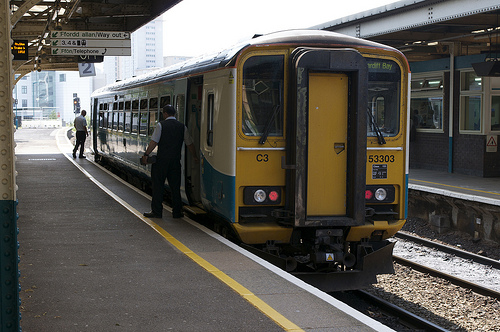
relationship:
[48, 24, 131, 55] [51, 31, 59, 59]
sign has arrows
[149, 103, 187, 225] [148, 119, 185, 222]
man wearing uniform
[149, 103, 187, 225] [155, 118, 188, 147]
man wearing shirt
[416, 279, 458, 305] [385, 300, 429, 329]
gravel between tracks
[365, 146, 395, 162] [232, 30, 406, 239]
numbers on train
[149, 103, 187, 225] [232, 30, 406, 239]
man outside train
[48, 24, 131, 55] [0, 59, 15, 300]
sign on building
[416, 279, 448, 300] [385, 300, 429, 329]
gravel on tracks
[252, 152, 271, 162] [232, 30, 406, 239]
writing on train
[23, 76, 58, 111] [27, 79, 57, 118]
building in background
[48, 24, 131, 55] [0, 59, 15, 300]
signs hanging from building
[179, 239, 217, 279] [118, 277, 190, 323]
line in pavemenet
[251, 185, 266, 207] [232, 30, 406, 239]
headlight of train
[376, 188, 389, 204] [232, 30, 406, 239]
headlight of train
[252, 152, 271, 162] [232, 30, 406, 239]
sign on train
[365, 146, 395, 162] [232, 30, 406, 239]
number on train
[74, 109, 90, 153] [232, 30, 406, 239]
man ready to board train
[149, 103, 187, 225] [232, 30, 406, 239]
man at back of train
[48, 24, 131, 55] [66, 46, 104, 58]
sign showing location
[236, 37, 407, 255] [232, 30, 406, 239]
front of train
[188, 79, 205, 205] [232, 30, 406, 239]
door of train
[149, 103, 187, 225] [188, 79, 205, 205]
man by door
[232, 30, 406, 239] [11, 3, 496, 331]
train at platform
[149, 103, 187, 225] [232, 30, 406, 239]
man next to train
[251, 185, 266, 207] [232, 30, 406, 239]
headlight on a train